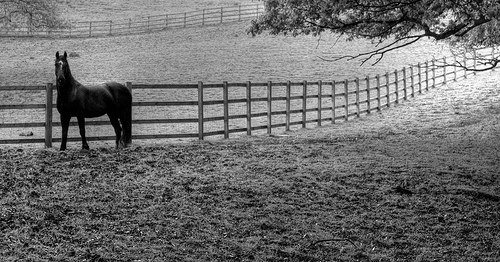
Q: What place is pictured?
A: It is a field.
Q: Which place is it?
A: It is a field.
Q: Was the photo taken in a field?
A: Yes, it was taken in a field.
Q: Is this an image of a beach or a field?
A: It is showing a field.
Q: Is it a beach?
A: No, it is a field.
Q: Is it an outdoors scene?
A: Yes, it is outdoors.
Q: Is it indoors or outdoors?
A: It is outdoors.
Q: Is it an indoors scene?
A: No, it is outdoors.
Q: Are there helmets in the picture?
A: No, there are no helmets.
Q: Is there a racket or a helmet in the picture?
A: No, there are no helmets or rackets.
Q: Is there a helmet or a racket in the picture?
A: No, there are no helmets or rackets.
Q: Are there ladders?
A: No, there are no ladders.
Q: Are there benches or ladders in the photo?
A: No, there are no ladders or benches.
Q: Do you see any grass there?
A: Yes, there is grass.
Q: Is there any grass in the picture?
A: Yes, there is grass.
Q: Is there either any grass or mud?
A: Yes, there is grass.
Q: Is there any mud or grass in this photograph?
A: Yes, there is grass.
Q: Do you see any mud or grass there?
A: Yes, there is grass.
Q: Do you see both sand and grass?
A: No, there is grass but no sand.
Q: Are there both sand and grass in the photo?
A: No, there is grass but no sand.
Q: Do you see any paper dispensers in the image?
A: No, there are no paper dispensers.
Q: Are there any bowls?
A: No, there are no bowls.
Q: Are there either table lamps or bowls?
A: No, there are no bowls or table lamps.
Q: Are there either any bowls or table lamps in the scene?
A: No, there are no bowls or table lamps.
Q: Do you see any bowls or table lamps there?
A: No, there are no bowls or table lamps.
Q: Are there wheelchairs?
A: No, there are no wheelchairs.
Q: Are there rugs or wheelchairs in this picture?
A: No, there are no wheelchairs or rugs.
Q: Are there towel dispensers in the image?
A: No, there are no towel dispensers.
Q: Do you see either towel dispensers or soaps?
A: No, there are no towel dispensers or soaps.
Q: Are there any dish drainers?
A: No, there are no dish drainers.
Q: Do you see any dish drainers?
A: No, there are no dish drainers.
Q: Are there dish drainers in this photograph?
A: No, there are no dish drainers.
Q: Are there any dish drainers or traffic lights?
A: No, there are no dish drainers or traffic lights.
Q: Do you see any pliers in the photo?
A: No, there are no pliers.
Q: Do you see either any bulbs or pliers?
A: No, there are no pliers or bulbs.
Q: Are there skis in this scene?
A: No, there are no skis.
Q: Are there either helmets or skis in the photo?
A: No, there are no skis or helmets.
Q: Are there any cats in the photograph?
A: No, there are no cats.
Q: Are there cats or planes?
A: No, there are no cats or planes.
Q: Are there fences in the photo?
A: Yes, there is a fence.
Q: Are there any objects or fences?
A: Yes, there is a fence.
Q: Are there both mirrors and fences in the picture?
A: No, there is a fence but no mirrors.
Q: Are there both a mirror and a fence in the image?
A: No, there is a fence but no mirrors.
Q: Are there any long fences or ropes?
A: Yes, there is a long fence.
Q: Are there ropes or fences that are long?
A: Yes, the fence is long.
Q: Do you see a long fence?
A: Yes, there is a long fence.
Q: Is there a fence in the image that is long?
A: Yes, there is a fence that is long.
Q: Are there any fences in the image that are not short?
A: Yes, there is a long fence.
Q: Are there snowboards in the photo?
A: No, there are no snowboards.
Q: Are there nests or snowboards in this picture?
A: No, there are no snowboards or nests.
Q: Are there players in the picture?
A: No, there are no players.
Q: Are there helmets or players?
A: No, there are no players or helmets.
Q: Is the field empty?
A: Yes, the field is empty.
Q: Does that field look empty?
A: Yes, the field is empty.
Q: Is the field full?
A: No, the field is empty.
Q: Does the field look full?
A: No, the field is empty.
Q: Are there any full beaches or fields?
A: No, there is a field but it is empty.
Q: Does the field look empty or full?
A: The field is empty.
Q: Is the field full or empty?
A: The field is empty.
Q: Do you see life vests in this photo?
A: No, there are no life vests.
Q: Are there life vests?
A: No, there are no life vests.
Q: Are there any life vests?
A: No, there are no life vests.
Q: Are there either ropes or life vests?
A: No, there are no life vests or ropes.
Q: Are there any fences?
A: Yes, there is a fence.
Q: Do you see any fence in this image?
A: Yes, there is a fence.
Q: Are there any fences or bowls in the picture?
A: Yes, there is a fence.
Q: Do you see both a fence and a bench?
A: No, there is a fence but no benches.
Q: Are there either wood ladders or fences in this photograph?
A: Yes, there is a wood fence.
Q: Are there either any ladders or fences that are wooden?
A: Yes, the fence is wooden.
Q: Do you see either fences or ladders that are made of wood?
A: Yes, the fence is made of wood.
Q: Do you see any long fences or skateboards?
A: Yes, there is a long fence.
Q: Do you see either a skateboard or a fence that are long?
A: Yes, the fence is long.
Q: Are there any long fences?
A: Yes, there is a long fence.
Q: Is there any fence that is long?
A: Yes, there is a fence that is long.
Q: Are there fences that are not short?
A: Yes, there is a long fence.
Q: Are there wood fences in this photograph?
A: Yes, there is a wood fence.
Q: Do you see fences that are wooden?
A: Yes, there is a fence that is wooden.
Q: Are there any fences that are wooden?
A: Yes, there is a fence that is wooden.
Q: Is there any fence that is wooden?
A: Yes, there is a fence that is wooden.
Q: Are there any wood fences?
A: Yes, there is a fence that is made of wood.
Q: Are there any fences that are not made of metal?
A: Yes, there is a fence that is made of wood.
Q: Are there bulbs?
A: No, there are no bulbs.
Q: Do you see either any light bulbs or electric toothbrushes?
A: No, there are no light bulbs or electric toothbrushes.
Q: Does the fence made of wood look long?
A: Yes, the fence is long.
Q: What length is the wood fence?
A: The fence is long.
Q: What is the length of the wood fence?
A: The fence is long.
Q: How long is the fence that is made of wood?
A: The fence is long.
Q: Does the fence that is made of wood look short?
A: No, the fence is long.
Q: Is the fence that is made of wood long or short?
A: The fence is long.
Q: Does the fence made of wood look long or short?
A: The fence is long.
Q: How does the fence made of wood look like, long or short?
A: The fence is long.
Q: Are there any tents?
A: No, there are no tents.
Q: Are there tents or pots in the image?
A: No, there are no tents or pots.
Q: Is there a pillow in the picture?
A: No, there are no pillows.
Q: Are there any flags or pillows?
A: No, there are no pillows or flags.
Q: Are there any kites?
A: No, there are no kites.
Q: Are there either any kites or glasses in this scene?
A: No, there are no kites or glasses.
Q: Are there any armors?
A: No, there are no armors.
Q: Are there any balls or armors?
A: No, there are no armors or balls.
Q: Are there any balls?
A: No, there are no balls.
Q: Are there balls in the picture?
A: No, there are no balls.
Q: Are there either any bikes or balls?
A: No, there are no balls or bikes.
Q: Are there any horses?
A: Yes, there is a horse.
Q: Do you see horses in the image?
A: Yes, there is a horse.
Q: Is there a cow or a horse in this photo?
A: Yes, there is a horse.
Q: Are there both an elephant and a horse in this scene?
A: No, there is a horse but no elephants.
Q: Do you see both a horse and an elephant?
A: No, there is a horse but no elephants.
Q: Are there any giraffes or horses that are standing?
A: Yes, the horse is standing.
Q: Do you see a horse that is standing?
A: Yes, there is a horse that is standing.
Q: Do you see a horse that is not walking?
A: Yes, there is a horse that is standing .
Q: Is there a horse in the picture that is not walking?
A: Yes, there is a horse that is standing.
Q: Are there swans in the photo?
A: No, there are no swans.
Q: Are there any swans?
A: No, there are no swans.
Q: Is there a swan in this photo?
A: No, there are no swans.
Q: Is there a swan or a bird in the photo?
A: No, there are no swans or birds.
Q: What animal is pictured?
A: The animal is a horse.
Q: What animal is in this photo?
A: The animal is a horse.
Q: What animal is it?
A: The animal is a horse.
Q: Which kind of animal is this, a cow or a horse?
A: This is a horse.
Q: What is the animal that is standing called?
A: The animal is a horse.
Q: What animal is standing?
A: The animal is a horse.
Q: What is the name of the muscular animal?
A: The animal is a horse.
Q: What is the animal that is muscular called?
A: The animal is a horse.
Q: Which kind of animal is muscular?
A: The animal is a horse.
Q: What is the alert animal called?
A: The animal is a horse.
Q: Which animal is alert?
A: The animal is a horse.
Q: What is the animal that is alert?
A: The animal is a horse.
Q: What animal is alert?
A: The animal is a horse.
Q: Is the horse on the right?
A: No, the horse is on the left of the image.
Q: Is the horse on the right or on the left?
A: The horse is on the left of the image.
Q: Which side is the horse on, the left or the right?
A: The horse is on the left of the image.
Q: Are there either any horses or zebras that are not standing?
A: No, there is a horse but it is standing.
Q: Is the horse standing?
A: Yes, the horse is standing.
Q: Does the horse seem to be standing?
A: Yes, the horse is standing.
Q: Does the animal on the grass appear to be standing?
A: Yes, the horse is standing.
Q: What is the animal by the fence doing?
A: The horse is standing.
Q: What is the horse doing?
A: The horse is standing.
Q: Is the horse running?
A: No, the horse is standing.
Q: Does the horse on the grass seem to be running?
A: No, the horse is standing.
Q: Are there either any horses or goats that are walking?
A: No, there is a horse but it is standing.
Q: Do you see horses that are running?
A: No, there is a horse but it is standing.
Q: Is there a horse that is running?
A: No, there is a horse but it is standing.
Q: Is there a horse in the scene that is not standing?
A: No, there is a horse but it is standing.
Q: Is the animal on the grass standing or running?
A: The horse is standing.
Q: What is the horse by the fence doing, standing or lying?
A: The horse is standing.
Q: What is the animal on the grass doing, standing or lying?
A: The horse is standing.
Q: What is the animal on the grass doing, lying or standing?
A: The horse is standing.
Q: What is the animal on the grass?
A: The animal is a horse.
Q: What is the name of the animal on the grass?
A: The animal is a horse.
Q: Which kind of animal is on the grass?
A: The animal is a horse.